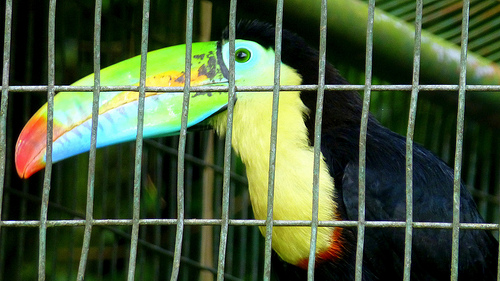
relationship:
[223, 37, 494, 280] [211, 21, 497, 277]
body on body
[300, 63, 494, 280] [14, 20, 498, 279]
body of bird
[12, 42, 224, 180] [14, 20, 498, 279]
beak of a bird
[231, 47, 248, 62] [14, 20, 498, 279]
bird eye of a bird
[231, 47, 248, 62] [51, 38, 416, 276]
bird eye of a bird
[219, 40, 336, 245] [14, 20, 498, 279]
neck of a bird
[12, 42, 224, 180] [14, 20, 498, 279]
beak of bird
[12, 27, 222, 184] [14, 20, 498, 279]
beck of bird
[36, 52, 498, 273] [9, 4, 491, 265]
bird in cage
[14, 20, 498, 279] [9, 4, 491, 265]
bird in cage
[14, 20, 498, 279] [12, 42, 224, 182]
bird with beak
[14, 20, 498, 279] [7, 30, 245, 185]
bird with beak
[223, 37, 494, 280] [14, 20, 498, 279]
body of bird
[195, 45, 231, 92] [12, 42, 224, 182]
chipped area of beak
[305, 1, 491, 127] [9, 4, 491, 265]
pipe above cage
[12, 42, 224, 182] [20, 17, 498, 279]
beak of tucan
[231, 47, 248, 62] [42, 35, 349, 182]
bird eye of toucan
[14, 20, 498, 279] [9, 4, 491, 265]
bird has cage